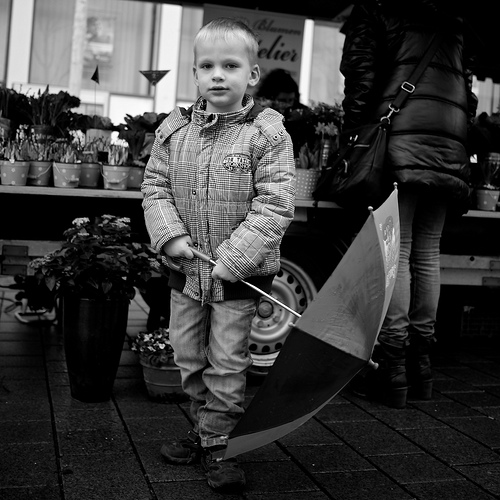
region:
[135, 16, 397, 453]
a child standing on the sidewalk holding an umbrella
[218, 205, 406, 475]
an umbrella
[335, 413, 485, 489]
squared pattern of a sidewalk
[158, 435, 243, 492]
a child's tennis shoes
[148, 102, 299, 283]
a child's jacket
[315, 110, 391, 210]
a woman's handbag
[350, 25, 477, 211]
a woman's down jacket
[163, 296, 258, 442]
a child's jeans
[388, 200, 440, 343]
a woman's jeans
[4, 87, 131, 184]
several plants being displayed on a cart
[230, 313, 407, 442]
black section of umbrella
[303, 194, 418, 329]
white section of the umbrella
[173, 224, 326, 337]
silver handle on the umbrella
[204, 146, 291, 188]
small insignia on coat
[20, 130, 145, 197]
flower pots on table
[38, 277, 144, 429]
large black pot on ground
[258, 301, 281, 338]
large silver lug in wheel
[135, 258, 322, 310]
black trim on child's coat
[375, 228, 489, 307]
wrinkles in woman's pants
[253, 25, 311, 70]
black words overhead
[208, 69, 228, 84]
A Young boy's nose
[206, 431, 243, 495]
A Young boy's shoe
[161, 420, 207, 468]
A Young boy's shoe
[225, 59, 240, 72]
A Young boy's eye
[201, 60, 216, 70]
A Young boy's eye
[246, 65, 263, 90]
A Young boy's ear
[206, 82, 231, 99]
A Young boy's mouth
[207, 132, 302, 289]
A Young boy's hand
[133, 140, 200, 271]
A Young boy's hand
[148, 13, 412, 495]
A Young boy holding an umbrella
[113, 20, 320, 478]
a very young boy wearing a heavy jacket and holding an umbrella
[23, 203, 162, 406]
a large potted plant on the ground next to the boy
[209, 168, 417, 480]
an umbrella with several colors the boy is holding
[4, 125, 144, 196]
several plants lined up in polka dotted pots on a table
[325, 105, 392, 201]
a black woman's purse someone is carrying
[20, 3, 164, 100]
the large window on a building in the background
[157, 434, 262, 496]
the boy's dark shoes he is wearing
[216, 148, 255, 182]
a patch sewn on the front of the boys jacket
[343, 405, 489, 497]
the brick ground appears to be wet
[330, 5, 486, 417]
a female standing behind the boy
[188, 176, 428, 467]
multi colored umbrella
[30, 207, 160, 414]
large vase of flowers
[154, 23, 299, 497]
towheaded boy in a winter coat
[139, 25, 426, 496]
blond boy holding an umbrella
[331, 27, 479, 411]
woman in a black winter coat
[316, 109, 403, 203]
black purse on a ladies shoulder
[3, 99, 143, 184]
small pots of herbs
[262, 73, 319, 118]
brunette lady selling flowers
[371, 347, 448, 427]
black platform boots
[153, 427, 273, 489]
velcro strapped sneakers for boys